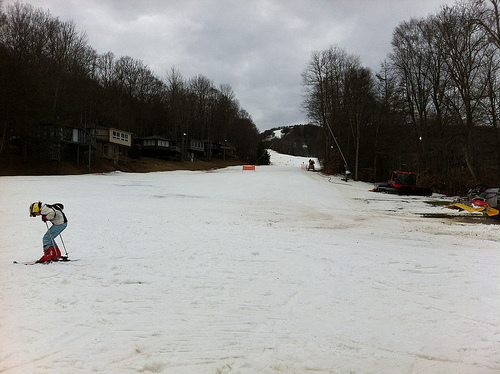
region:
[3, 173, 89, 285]
One person skiing the slope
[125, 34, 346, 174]
Very cloudy day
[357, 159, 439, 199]
Snow pusher parked to the side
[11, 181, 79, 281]
Skiier is bent over looking at something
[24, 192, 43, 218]
Yellow helmet for skiing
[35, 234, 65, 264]
Ski boots that are orange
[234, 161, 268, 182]
Orange ski gate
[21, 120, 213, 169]
Row of houses near the slope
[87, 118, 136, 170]
Tan colored house next to the slope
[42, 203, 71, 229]
Black and white ski jacket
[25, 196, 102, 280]
the person is bending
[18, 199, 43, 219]
the helmet is yellow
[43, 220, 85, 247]
the pants are green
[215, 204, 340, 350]
floor is covered with snow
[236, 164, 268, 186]
the flag is orange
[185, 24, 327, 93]
the sky is cloudy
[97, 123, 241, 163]
houses are in the background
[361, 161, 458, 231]
the snow mobile is re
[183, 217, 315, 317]
ski trail is on the snow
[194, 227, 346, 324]
the snow is white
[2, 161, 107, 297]
a child is skiing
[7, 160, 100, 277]
the kid is holding the ski poles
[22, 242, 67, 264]
the ski boots are red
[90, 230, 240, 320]
foot prints in the snow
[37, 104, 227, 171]
houses on the left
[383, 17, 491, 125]
the trees are bare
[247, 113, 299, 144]
snow in the mountain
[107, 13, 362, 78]
the sky is overcast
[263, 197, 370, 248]
the snow is dirty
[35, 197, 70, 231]
the coat is black and white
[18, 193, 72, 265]
person skiing in the snoqw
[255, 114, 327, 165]
tall hill shown between trees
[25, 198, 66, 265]
skier wearing a yellow hat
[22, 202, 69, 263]
skier wearing blue pants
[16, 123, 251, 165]
row of houses in the trees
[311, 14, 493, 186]
tall leafless trees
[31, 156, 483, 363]
field of snow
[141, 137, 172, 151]
house with wrap around windows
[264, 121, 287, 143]
patch of snow on a hill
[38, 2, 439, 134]
grey cloudy sky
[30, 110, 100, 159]
This is a house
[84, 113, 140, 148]
This is a house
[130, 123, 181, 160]
This is a house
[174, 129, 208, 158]
This is a house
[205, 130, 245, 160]
This is a house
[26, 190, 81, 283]
This is a person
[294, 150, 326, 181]
This is a person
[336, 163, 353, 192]
This is a person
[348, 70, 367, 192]
This is a tree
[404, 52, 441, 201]
This is a tree